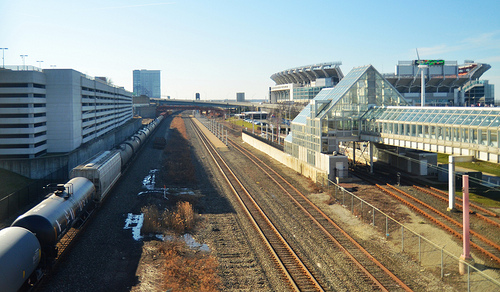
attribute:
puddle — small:
[124, 210, 144, 241]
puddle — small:
[152, 231, 211, 257]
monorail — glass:
[361, 104, 499, 215]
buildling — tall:
[131, 69, 162, 102]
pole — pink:
[461, 175, 470, 258]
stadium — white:
[269, 58, 496, 107]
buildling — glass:
[282, 66, 417, 168]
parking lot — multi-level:
[2, 67, 141, 181]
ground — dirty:
[0, 105, 499, 291]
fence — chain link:
[315, 174, 500, 292]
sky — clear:
[1, 2, 499, 101]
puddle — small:
[177, 191, 198, 195]